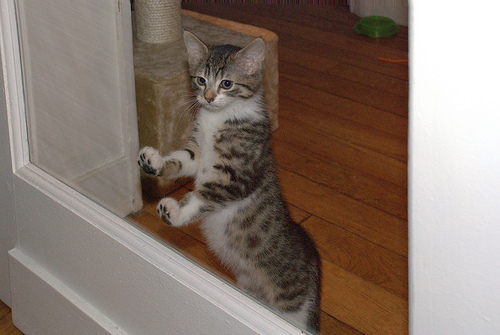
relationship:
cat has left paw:
[135, 32, 319, 330] [159, 194, 183, 228]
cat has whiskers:
[135, 32, 319, 330] [176, 87, 205, 118]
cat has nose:
[135, 32, 319, 330] [204, 92, 216, 103]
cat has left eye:
[135, 32, 319, 330] [220, 80, 234, 92]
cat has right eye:
[135, 32, 319, 330] [196, 75, 207, 88]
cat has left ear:
[135, 32, 319, 330] [240, 37, 271, 74]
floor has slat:
[112, 1, 404, 334] [277, 77, 407, 137]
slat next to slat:
[278, 60, 405, 121] [276, 36, 415, 96]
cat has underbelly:
[135, 32, 319, 330] [192, 118, 263, 291]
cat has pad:
[135, 32, 319, 330] [142, 152, 147, 160]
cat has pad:
[135, 32, 319, 330] [146, 158, 152, 166]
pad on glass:
[156, 205, 162, 215] [13, 1, 411, 333]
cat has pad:
[135, 32, 319, 330] [161, 213, 172, 225]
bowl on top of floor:
[350, 15, 396, 40] [112, 1, 404, 334]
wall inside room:
[348, 1, 411, 31] [18, 2, 409, 333]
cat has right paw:
[135, 32, 319, 330] [135, 146, 162, 180]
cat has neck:
[135, 32, 319, 330] [197, 99, 263, 126]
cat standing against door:
[135, 32, 319, 330] [2, 4, 422, 334]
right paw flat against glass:
[135, 146, 162, 180] [13, 1, 411, 333]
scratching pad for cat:
[134, 1, 189, 51] [135, 32, 319, 330]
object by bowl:
[367, 52, 409, 65] [350, 15, 396, 40]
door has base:
[2, 4, 422, 334] [13, 149, 299, 334]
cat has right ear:
[135, 32, 319, 330] [179, 32, 213, 63]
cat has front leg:
[135, 32, 319, 330] [137, 117, 210, 185]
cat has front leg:
[135, 32, 319, 330] [158, 134, 264, 229]